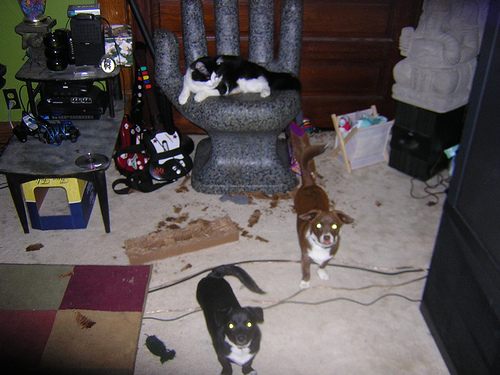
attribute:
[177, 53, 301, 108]
cat — black, white, resting, furry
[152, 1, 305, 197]
hand chair — grayish, hand-shaped, hand shaped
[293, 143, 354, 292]
dog — brown, white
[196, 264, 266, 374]
dog — black, white, standing, bratty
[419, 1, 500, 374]
television — big screen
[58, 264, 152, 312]
rug square — burgundy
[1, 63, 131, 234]
table — gray, multi level, cluttered, grey, black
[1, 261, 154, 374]
rug — multi colored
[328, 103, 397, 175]
container — for small toys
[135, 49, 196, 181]
guitar — hero controller, standing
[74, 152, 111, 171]
disc — shiny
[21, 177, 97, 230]
box — cardboard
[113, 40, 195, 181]
guitars — guitar hero